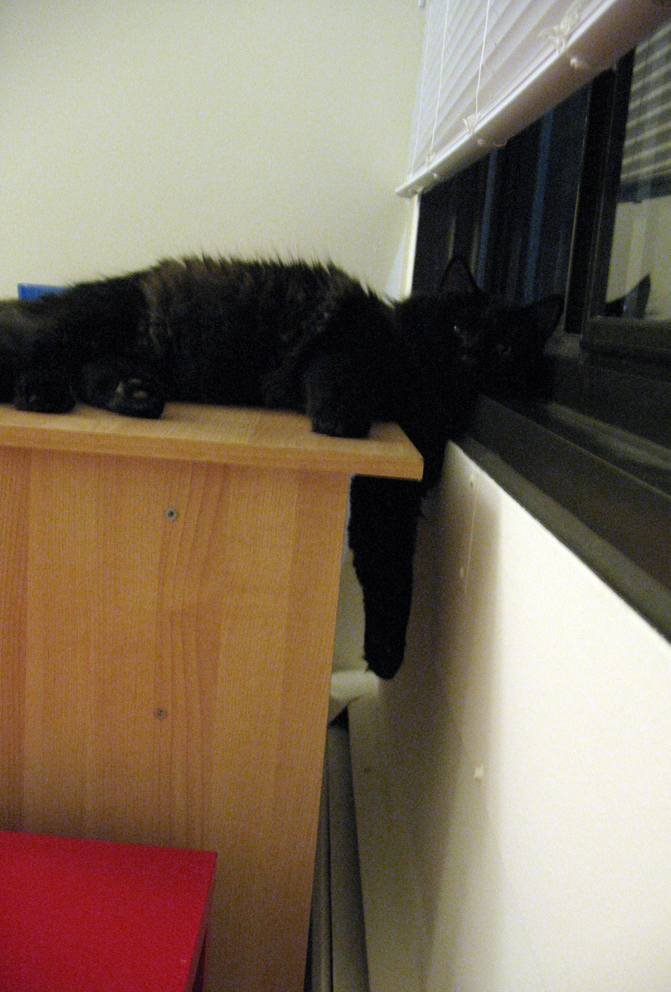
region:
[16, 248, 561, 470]
it is a black cat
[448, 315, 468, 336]
it is the eye of the cat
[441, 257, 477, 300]
it is the ear of the cat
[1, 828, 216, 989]
a red folder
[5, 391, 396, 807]
a brown table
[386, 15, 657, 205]
they are white blinds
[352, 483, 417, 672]
it is the arm of the cat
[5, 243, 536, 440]
a black cat is laying down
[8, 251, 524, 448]
it is a lazy cat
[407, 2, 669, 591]
window in front of cat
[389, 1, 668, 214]
white blinds in front of window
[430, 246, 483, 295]
black ear of cat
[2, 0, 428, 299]
tan wall behind wooden chest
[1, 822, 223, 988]
red mini wooden roof leaning against wooden chest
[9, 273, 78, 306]
blue object behind cat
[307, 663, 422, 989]
beige vent near bottom of wall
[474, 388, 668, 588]
back window sill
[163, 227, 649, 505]
Cat sitting on a table.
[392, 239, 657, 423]
Ears on the cat.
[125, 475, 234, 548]
Screw on the wood.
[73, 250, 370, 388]
Fur on the cat.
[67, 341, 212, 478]
Foot on the cat.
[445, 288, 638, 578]
Sill on the window.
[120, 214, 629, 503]
Black furry cat.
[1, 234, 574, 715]
cat laying on a table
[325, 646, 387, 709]
paw is white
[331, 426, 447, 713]
arm is hanging off the table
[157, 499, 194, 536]
small screw in the table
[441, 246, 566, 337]
two pointy black ears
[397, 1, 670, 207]
white blinds on the window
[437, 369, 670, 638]
the window sill is black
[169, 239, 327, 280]
tufts of black hair sticking up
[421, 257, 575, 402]
head is resting on the window sill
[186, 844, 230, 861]
corner of a red table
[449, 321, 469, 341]
a black cat's right eye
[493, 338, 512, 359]
a black cat's left eye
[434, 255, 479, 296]
a black cat's right ear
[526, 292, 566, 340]
a black cat's left ear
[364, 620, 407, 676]
a black cat's left paw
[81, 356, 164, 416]
a black cat's left foot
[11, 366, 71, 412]
a black cat's right foot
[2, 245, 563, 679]
long haired black cat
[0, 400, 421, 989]
light stained wood dresser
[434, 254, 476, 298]
ear belongs to cat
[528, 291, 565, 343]
ear belongs to cat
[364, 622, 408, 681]
paw belongs to cat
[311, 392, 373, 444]
paw belongs to cat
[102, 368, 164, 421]
paw belongs to cat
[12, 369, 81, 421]
paw belongs to cat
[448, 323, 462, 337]
eye belongs to cat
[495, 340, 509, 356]
eye belongs to cat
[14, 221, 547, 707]
cat laying on the table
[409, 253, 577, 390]
cat head on the window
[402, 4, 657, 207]
white blinds on the window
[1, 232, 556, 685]
black cat on the desk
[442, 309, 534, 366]
black cat with black eyes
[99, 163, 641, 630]
a cat laying on the desk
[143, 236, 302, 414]
a black cat laying on the desk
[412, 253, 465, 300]
an ear on the cat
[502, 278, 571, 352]
an ear on the cat